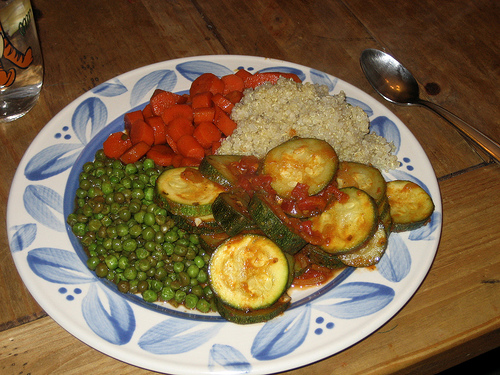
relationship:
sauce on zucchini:
[235, 173, 312, 219] [153, 141, 430, 321]